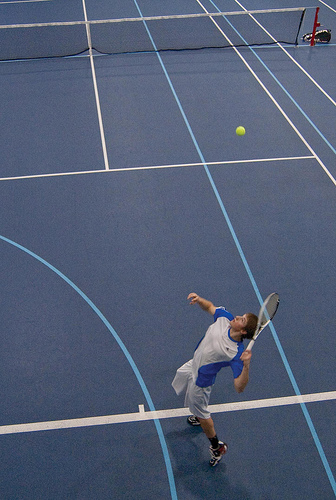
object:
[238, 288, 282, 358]
tennis racket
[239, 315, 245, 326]
eyes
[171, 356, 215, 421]
shorts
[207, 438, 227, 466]
foot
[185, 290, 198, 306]
hand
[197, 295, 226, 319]
arm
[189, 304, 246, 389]
shirt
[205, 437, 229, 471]
shoes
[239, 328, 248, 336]
ear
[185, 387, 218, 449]
leg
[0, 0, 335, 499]
tennis court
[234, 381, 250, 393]
elbow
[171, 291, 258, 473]
player